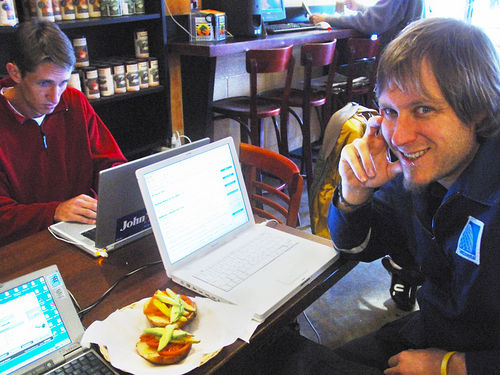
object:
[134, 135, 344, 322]
laptop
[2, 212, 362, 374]
table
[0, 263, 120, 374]
laptop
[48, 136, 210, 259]
laptop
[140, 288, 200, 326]
toast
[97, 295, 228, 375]
plate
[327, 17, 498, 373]
man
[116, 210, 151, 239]
sticker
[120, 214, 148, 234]
"john"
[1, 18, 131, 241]
man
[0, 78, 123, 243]
shirt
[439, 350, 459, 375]
band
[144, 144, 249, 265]
screen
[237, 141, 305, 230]
chair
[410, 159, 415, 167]
piercing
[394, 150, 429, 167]
lip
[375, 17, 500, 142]
hair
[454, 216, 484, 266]
logo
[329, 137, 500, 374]
jacket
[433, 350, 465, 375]
wrist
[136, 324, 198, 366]
food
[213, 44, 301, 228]
bar stool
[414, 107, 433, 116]
eye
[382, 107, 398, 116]
eye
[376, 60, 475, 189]
face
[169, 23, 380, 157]
bar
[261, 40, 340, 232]
bar stool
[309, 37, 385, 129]
bar stool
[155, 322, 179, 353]
avocado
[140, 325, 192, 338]
avocado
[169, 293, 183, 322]
avocado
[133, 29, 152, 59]
jar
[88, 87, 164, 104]
shelf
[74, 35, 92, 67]
jar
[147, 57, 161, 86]
jar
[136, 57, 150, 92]
jar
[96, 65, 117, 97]
jar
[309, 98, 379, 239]
rain jacket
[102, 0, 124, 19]
tea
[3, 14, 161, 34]
shelf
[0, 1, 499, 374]
coffee shop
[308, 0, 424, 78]
man